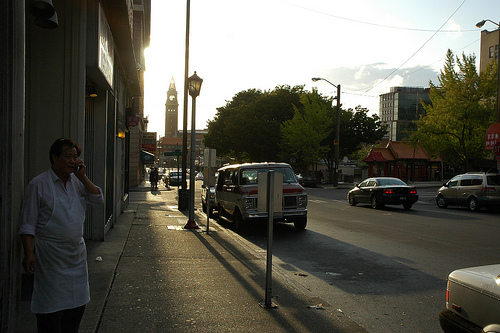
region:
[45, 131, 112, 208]
Man on a phone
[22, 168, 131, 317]
Apron on a man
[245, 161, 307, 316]
silver sign post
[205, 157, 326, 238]
Van parked by a sidewalk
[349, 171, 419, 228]
Black car in a road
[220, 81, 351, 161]
Green leaves on a tree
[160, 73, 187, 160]
Clock tower by a road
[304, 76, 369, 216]
Light by a road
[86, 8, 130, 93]
Sign by a building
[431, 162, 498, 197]
Tan van on a road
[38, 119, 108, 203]
man on cell phone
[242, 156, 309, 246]
traffic sign on side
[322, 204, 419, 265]
reflection on the road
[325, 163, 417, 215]
black sedan is driving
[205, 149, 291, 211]
red truck is parked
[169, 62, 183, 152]
clock tower in distance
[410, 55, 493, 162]
bright trees in background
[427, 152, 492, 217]
beige van is parked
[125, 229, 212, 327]
dirty sidewalk that is old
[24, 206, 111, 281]
white apron on man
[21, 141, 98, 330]
CHEF TAKING A BREAK ON PHONE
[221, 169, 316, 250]
VEHICLE PARKED ON PAVED ROAD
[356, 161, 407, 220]
VEHICLE DRIVING ON PAVED ROAD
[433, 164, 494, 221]
VEHICLE PARKED ON PAVED ROAD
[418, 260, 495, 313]
VEHICLE PARKED ON PAVED ROAD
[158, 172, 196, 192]
VEHICLE PARKED ON PAVED ROAD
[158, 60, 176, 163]
CLOCK TOWER OFF IN DISTANCE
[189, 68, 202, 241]
STREET LAMP ON LEFT OF ROAD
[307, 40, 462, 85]
CLOUDS ON A SUNNY DAY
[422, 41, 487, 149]
GREEN TREE ON RIGHT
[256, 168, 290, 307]
a small parking sign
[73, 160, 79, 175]
a small phone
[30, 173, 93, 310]
a long white apron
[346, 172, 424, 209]
a small car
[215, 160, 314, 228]
a red and white van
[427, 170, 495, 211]
a small brown van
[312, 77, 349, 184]
a tall light pole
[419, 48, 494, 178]
a tall green tree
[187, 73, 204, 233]
a black light pole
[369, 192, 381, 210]
the wheel of a car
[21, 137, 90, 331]
a man in a white apron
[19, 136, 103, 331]
a man talking on the phone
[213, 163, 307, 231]
a white and red van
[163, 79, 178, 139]
a clock tower in the background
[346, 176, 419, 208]
a small black car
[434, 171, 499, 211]
a tan parked van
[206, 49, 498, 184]
Green trees in the background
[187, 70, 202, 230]
an old street light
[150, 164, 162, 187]
a couple of people walking on the sidewalk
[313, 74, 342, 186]
a tall street light